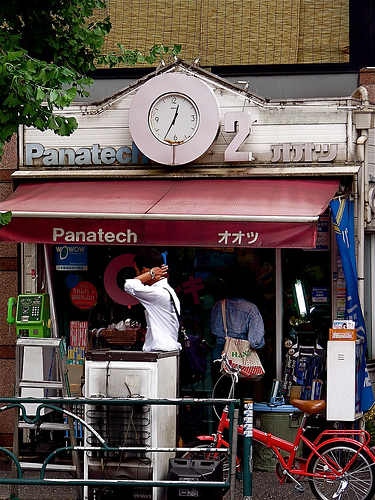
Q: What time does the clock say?
A: 12:35.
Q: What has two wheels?
A: Red bicycle.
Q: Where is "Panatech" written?
A: On red awning.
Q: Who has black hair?
A: Man in white shirt.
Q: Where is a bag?
A: Around woman's shoulder.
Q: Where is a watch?
A: Around man's wrist.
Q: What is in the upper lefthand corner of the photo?
A: A green tree.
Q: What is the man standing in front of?
A: An old white refrigerator.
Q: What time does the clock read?
A: 1:35.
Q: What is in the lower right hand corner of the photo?
A: A red bicycle.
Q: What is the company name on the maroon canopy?
A: Panatech.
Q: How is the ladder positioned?
A: Leaning against the railing.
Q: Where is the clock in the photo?
A: On the front of the business.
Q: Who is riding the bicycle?
A: No one is riding the bicycle.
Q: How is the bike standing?
A: A kickstand.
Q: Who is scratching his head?
A: The man in white.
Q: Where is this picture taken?
A: Panatech.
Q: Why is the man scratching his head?
A: He has an itch.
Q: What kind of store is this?
A: A chinese store.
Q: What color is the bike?
A: Red.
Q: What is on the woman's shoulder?
A: A purse.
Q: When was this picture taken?
A: Daytime.